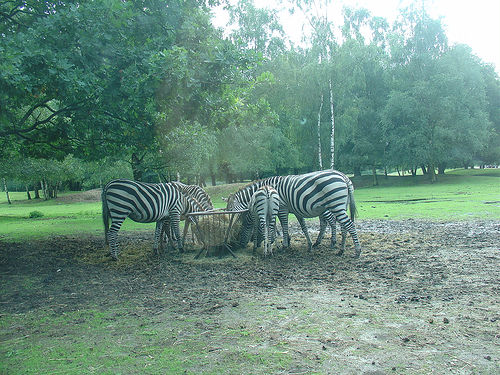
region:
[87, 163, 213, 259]
striped zebra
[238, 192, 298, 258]
striped zebra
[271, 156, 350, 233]
striped zebra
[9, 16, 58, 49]
green leaves in brown trees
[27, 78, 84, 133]
green leaves in brown trees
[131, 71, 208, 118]
green leaves in brown trees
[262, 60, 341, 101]
green leaves in brown trees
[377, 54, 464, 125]
green leaves in brown trees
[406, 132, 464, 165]
green leaves in brown trees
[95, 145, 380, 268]
The zebras are gathered around a trough.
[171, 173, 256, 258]
The zebras are eating.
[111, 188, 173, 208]
The zebra has black and white stripes.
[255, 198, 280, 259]
The zebra has two back legs.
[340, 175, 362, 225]
The zebra has a tail.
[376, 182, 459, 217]
The grass is green.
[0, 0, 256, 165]
The leaves on the tree are green.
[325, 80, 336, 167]
The trunk of a tree.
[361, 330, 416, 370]
A patch of dirt on the ground.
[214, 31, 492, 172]
Trees in the distance.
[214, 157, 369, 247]
striped zebra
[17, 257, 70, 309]
short brown and green grass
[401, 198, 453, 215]
short brown and green grass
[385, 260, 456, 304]
short brown and green grass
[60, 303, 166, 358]
short brown and green grass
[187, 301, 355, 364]
short brown and green grass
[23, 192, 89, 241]
short brown and green grass in enclosure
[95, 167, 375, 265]
Group of zebras eating hay from a trough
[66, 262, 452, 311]
Zebra poop piled up on the ground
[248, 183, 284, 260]
Young zebra eating from a hay trough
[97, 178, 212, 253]
Adult zebras eating from a hay trough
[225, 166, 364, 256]
Adult zebra eating from a hay trough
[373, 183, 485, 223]
Grassy field in the background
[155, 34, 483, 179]
Lush green trees in the background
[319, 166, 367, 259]
Hind legs of an adult zebra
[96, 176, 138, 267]
Hind legs of an adult zebra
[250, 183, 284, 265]
Hind legs of an young zebra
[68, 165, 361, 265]
zebras eating from a trough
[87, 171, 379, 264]
zebras eating hay together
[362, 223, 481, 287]
dirt disturbed from hoof activity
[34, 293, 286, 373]
patchy grass and dirt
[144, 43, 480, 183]
small grove of green trees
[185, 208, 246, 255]
a metal trough full of hay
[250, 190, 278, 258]
a young stiped zebra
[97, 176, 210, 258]
a mature grazing zebra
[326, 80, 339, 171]
white trunk of a birch tree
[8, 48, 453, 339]
zebras grazing under a tree